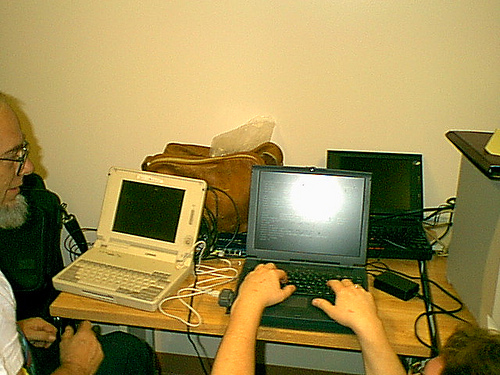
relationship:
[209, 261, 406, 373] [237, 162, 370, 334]
hands on laptop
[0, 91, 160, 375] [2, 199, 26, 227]
man has hair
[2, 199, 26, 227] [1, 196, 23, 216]
hair on chin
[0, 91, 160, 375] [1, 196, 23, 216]
man has chin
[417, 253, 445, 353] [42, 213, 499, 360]
space between tables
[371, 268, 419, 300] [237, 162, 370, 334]
cord used on laptop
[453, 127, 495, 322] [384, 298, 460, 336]
container on desk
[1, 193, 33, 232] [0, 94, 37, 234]
beard on man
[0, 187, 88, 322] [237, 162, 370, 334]
bag carries laptop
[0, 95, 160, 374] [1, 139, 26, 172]
man wears glasses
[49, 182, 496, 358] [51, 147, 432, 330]
table has laptops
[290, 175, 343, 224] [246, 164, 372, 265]
glare on computer screen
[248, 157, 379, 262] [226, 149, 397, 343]
computer screen on lap top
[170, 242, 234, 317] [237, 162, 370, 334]
white wires from laptop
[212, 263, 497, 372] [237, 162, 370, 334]
person inputting information into laptop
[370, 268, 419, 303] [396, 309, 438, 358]
power brick on table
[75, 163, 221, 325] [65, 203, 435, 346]
laptop in photo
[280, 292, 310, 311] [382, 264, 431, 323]
touchpad to help with scrolling